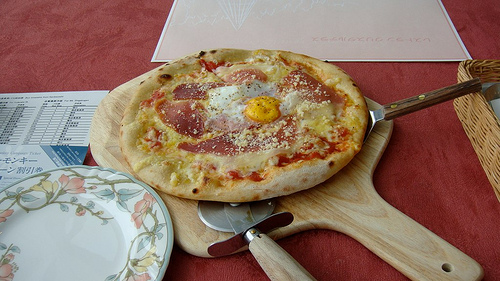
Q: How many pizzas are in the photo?
A: One.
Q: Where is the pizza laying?
A: Table.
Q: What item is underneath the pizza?
A: Wooden board.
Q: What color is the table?
A: Red.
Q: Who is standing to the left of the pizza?
A: No one.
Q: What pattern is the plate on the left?
A: Flowers.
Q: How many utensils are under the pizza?
A: Two.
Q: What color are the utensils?
A: Silver.